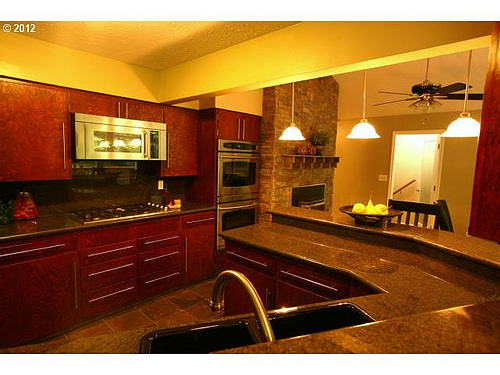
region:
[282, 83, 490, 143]
three lights hanging from ceiling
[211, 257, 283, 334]
faucet by the kitchen sink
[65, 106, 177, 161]
microwave above the stove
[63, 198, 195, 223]
in counter stove top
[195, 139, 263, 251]
two built in ovens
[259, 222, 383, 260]
beautiful granite counter tops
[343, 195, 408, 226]
bowl of fruit on counter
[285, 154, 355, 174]
shelf hanging on wall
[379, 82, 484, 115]
brown ceiling fan hanging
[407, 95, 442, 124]
light on the ceiling fan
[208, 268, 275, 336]
A pipe in the photo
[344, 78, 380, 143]
Lightings in the photo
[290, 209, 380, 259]
Shelves in the photo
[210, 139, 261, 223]
An oven in the photo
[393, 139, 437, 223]
A door in the photo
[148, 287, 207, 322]
Tiles in the photo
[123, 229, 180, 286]
Cabinets in the photo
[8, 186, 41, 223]
A toaster in the photo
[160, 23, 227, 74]
A ceiling in the photo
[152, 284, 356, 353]
A sink in the photo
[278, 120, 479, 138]
Lights are shining brightly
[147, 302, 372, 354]
The sink is black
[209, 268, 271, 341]
The faucet is silver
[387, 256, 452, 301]
The counter top is dark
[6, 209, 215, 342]
The cabinets are dark brown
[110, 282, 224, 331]
The floor has dark tiles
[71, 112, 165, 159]
The microwave is steel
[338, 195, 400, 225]
Some fruit in a basket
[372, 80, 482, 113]
Fan on the ceiling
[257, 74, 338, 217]
Fireplace made of bricks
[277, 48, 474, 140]
the three hanging lights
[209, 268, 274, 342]
the stainless steel kitchen faucet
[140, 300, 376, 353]
the double sink in the kitchen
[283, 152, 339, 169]
the mantle above the fireplace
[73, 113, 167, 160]
the stainless steel microwave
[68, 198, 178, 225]
the stovetop under the microwave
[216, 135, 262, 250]
the double ovens near the fireplace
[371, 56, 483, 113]
the hanging ceiling fan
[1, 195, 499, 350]
the countertops in the kitchen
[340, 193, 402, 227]
the bowl on the bar area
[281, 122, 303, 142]
Light descending from ceiling.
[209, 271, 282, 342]
Goose neck faucet on sink.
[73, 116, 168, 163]
Stainless steel microwave builtin.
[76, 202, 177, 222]
Gas topped cook stove.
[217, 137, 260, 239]
Two built in ovens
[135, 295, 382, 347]
Double sinks in kitchen.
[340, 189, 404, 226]
Fruit deco on top of counter.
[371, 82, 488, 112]
Ceiling fan in dining room.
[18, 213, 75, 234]
Granite top counter top.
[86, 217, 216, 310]
Brown modern kitchen cabinets.